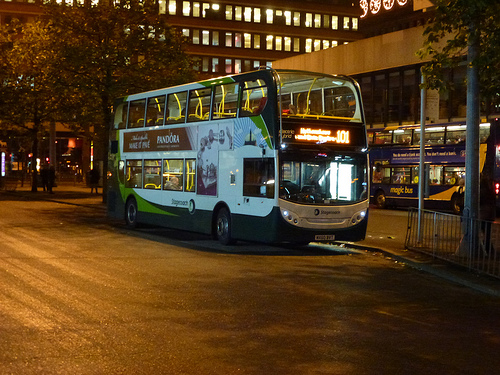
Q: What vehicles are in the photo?
A: Buses.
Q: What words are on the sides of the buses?
A: Pandora and magic bus.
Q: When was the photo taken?
A: Night time.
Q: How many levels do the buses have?
A: Two.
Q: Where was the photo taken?
A: Outdoors, urban setting.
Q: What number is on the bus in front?
A: 101.